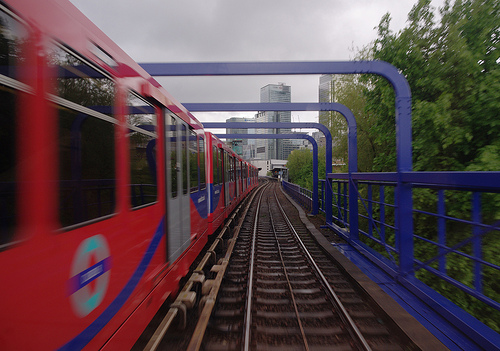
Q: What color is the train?
A: Red.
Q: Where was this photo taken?
A: On train tracks.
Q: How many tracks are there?
A: Two.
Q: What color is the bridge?
A: Blue.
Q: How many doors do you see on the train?
A: One.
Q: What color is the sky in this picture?
A: Grey.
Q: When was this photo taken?
A: During the day.